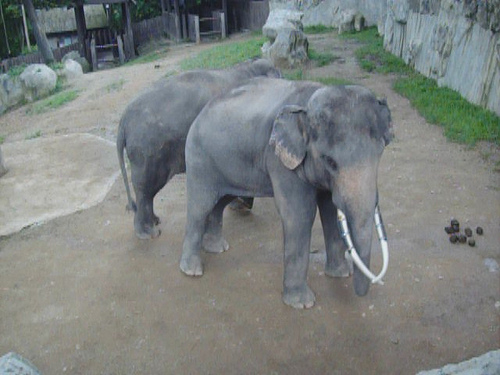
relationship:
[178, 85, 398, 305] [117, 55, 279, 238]
elephant beside elephant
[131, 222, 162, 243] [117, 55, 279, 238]
back feet on elephant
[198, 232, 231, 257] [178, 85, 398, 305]
back feet on elephant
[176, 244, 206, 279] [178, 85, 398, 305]
back feet on elephant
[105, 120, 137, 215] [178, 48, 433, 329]
tail on elephant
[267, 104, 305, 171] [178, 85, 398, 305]
ear on elephant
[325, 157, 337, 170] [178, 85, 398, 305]
eye on elephant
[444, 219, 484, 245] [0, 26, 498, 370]
dropping on ground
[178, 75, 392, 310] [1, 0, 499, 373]
elephant in pen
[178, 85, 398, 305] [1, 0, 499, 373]
elephant in pen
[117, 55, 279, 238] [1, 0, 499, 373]
elephant in pen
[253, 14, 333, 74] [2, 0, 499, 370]
rocks in exhibit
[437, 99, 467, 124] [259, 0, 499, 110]
grass by rocks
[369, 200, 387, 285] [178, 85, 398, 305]
tusk on elephant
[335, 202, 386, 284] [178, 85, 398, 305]
tusk on elephant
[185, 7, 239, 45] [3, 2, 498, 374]
gate on enclosure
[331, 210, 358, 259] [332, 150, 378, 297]
brace on trunk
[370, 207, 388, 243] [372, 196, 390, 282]
brace on tusk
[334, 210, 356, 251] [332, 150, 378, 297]
brace on trunk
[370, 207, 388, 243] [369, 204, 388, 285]
brace on tusk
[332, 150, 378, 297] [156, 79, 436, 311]
trunk on elephant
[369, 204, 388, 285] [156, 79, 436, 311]
tusk on elephant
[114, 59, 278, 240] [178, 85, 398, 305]
elephant behind elephant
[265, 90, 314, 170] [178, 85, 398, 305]
ear on elephant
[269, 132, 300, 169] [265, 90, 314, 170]
dirt on ear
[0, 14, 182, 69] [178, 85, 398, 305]
fence behind elephant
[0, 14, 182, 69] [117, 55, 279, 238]
fence behind elephant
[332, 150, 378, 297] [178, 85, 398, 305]
trunk on elephant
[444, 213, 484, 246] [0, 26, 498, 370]
dropping on ground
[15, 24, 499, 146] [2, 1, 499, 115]
grass growing along wall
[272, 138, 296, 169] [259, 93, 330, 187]
dirt on ear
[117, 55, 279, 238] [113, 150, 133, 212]
elephant has tail